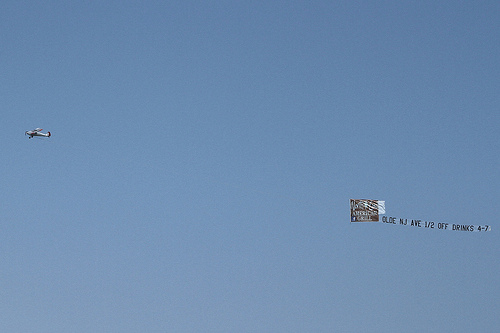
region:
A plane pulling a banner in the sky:
[0, 0, 499, 332]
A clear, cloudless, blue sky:
[1, 0, 499, 332]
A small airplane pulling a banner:
[24, 125, 491, 232]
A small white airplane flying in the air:
[24, 127, 51, 139]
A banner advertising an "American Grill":
[348, 196, 491, 232]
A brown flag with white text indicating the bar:
[349, 196, 379, 223]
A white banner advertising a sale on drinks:
[378, 213, 491, 233]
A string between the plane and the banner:
[33, 135, 350, 224]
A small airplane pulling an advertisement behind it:
[23, 125, 490, 232]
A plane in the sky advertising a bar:
[0, 0, 499, 332]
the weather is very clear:
[50, 48, 437, 328]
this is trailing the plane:
[319, 153, 499, 260]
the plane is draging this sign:
[317, 173, 472, 286]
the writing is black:
[372, 204, 497, 266]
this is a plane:
[13, 108, 131, 206]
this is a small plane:
[15, 111, 103, 184]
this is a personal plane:
[9, 95, 81, 195]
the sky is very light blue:
[59, 41, 405, 290]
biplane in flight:
[19, 117, 56, 147]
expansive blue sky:
[5, 1, 497, 327]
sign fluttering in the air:
[348, 192, 490, 245]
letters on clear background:
[376, 209, 491, 239]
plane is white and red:
[26, 124, 53, 144]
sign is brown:
[351, 198, 388, 225]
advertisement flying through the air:
[347, 193, 488, 243]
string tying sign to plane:
[48, 106, 354, 220]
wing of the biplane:
[33, 128, 51, 133]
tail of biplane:
[46, 131, 65, 138]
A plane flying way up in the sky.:
[21, 125, 59, 144]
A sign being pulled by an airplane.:
[345, 196, 494, 236]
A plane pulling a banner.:
[22, 122, 493, 238]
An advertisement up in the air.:
[379, 214, 492, 234]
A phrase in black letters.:
[377, 214, 492, 235]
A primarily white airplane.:
[23, 125, 53, 140]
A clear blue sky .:
[2, 1, 496, 329]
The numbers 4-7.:
[475, 223, 491, 235]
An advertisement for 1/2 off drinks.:
[420, 217, 471, 233]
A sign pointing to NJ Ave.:
[398, 215, 421, 225]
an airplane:
[20, 126, 56, 143]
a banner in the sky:
[334, 198, 491, 238]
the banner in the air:
[350, 195, 495, 243]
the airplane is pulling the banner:
[13, 130, 63, 138]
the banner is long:
[340, 194, 490, 236]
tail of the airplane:
[45, 128, 51, 138]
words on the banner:
[379, 215, 491, 231]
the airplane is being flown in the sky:
[15, 124, 66, 141]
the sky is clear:
[114, 195, 294, 285]